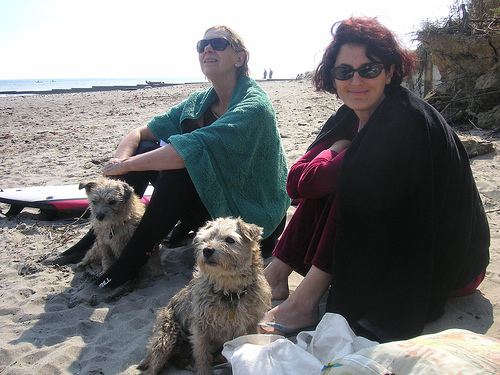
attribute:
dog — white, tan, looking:
[169, 221, 269, 341]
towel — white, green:
[250, 330, 380, 366]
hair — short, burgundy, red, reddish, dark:
[334, 31, 400, 59]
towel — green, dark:
[214, 103, 289, 202]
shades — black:
[324, 64, 397, 79]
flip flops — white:
[260, 314, 324, 337]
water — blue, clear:
[10, 81, 138, 94]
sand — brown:
[31, 96, 154, 135]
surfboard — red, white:
[3, 177, 92, 213]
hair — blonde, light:
[226, 25, 251, 54]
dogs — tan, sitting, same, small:
[58, 181, 279, 321]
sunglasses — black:
[186, 41, 240, 57]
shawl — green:
[210, 82, 283, 203]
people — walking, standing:
[264, 63, 283, 86]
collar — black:
[213, 287, 258, 301]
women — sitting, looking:
[106, 57, 482, 259]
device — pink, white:
[22, 184, 117, 215]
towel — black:
[358, 113, 452, 215]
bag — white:
[251, 336, 399, 372]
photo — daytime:
[31, 13, 475, 370]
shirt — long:
[285, 153, 346, 208]